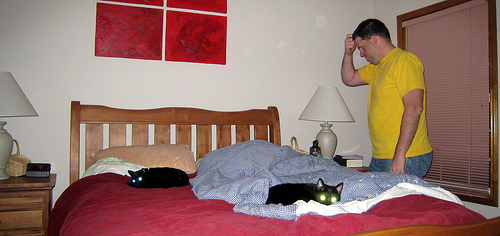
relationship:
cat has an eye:
[265, 178, 344, 206] [320, 195, 325, 201]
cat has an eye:
[265, 178, 344, 206] [331, 197, 336, 202]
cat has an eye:
[127, 167, 189, 190] [139, 177, 143, 181]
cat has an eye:
[127, 167, 189, 190] [132, 179, 136, 183]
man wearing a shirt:
[341, 18, 433, 178] [358, 46, 433, 159]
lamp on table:
[0, 71, 38, 180] [0, 174, 56, 236]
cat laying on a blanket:
[127, 167, 189, 190] [46, 170, 488, 235]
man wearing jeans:
[341, 18, 433, 178] [368, 152, 434, 179]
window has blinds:
[396, 0, 498, 208] [401, 0, 489, 200]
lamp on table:
[299, 87, 356, 160] [347, 165, 370, 172]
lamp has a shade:
[0, 71, 38, 180] [0, 72, 39, 117]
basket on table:
[4, 139, 31, 177] [0, 174, 56, 236]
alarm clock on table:
[26, 163, 51, 178] [0, 174, 56, 236]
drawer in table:
[0, 210, 43, 230] [0, 174, 56, 236]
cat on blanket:
[127, 167, 189, 190] [46, 170, 488, 235]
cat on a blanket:
[265, 178, 344, 206] [188, 139, 464, 221]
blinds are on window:
[401, 0, 489, 200] [396, 0, 498, 208]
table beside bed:
[347, 165, 370, 172] [47, 100, 500, 235]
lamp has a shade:
[299, 87, 356, 160] [298, 86, 355, 122]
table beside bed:
[0, 174, 56, 236] [47, 100, 500, 235]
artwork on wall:
[93, 0, 229, 67] [0, 0, 373, 210]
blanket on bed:
[46, 170, 488, 235] [47, 100, 500, 235]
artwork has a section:
[93, 0, 229, 67] [94, 2, 165, 61]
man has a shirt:
[341, 18, 433, 178] [358, 46, 433, 159]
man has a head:
[341, 18, 433, 178] [352, 18, 392, 65]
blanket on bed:
[188, 139, 464, 221] [47, 100, 500, 235]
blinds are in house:
[401, 0, 489, 200] [0, 0, 500, 236]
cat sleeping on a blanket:
[127, 167, 189, 190] [46, 170, 488, 235]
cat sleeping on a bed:
[265, 178, 344, 206] [47, 100, 500, 235]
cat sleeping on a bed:
[127, 167, 189, 190] [47, 100, 500, 235]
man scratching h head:
[341, 18, 433, 178] [352, 18, 392, 65]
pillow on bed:
[92, 144, 197, 174] [47, 100, 500, 235]